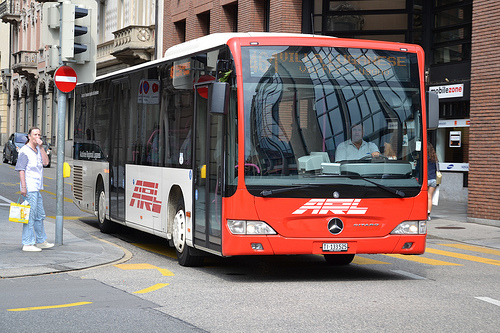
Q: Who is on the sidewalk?
A: A woman.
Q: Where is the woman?
A: The sidewalk.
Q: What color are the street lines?
A: Yellow.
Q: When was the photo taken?
A: Day time.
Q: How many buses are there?
A: One.